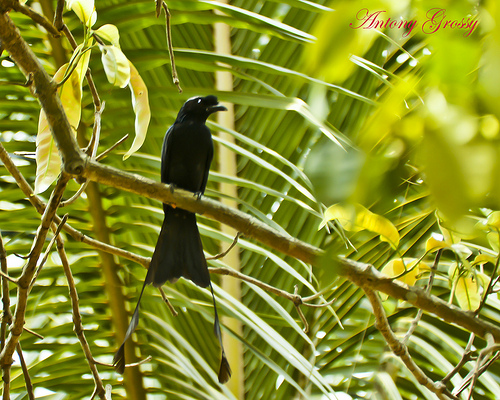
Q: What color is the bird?
A: Black.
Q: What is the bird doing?
A: Standing on a branch.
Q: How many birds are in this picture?
A: One.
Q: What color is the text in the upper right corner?
A: Red.